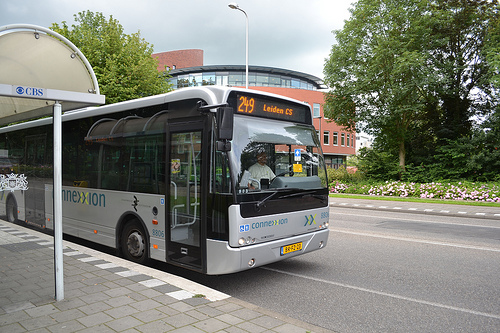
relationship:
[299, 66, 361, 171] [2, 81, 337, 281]
building behind bus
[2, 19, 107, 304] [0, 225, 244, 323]
shelter on sidewalk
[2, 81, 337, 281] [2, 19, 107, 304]
bus at bus stop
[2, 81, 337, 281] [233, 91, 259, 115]
bus number 249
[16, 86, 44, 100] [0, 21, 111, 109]
lettes cbs on awning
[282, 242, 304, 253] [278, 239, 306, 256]
license plate color yellow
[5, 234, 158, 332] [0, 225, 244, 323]
bricks on sidewalk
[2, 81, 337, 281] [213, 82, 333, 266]
bus on front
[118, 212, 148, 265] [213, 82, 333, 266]
tyre on front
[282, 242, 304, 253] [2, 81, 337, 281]
license plate on bus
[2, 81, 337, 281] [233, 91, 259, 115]
bus has a number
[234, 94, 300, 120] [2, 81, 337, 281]
display on bus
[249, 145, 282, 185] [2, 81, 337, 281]
driver of bus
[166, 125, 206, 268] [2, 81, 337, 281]
door of bus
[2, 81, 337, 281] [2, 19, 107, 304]
bus on front bus stop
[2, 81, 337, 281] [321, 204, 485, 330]
bus on road